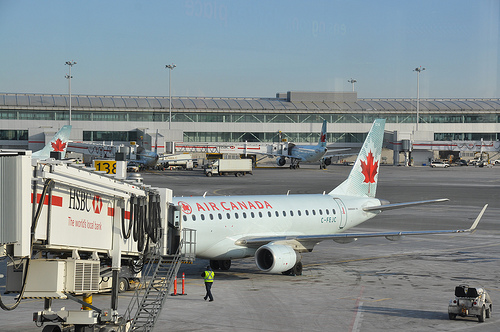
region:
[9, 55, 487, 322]
This is an airport scene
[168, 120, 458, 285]
This is an airliner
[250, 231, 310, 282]
This is one of the plane's engines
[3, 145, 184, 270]
This is a boarding tunnel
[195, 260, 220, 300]
This man is one of the ground crew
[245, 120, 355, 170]
Another plane is parked here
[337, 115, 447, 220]
This is the plane's tail section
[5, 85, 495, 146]
This is the terminal building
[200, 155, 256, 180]
A white truck is here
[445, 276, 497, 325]
A runway vehicle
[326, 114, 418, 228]
a red maple leaf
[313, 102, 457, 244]
the symbol of canada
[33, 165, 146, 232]
the hsbc logo on a runway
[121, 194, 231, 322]
this plane has a ladder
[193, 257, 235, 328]
a man in a safety jacket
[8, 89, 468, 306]
a plane at the terminal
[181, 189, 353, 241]
this is an air canada plane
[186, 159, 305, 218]
the font is red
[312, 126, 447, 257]
the logo on an airplane tail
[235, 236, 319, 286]
the engine of a jet plane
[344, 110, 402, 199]
Plane has red leaf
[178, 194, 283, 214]
Airplane says Air Canada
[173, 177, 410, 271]
Airplane is very white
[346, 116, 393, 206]
Tail fin has Canadian Red Maple leaf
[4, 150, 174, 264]
Plane loading chute is white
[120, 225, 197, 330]
Stairs to plane door are metal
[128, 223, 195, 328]
Stairs to plane door are gray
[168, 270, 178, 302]
Orange caution cone sitting on ground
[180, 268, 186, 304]
Orange caution cone sitting on ground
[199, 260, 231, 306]
Man wearing a bright green vest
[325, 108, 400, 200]
the tail of a plane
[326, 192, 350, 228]
the door of a plane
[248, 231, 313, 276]
the engine of a plane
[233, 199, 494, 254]
the wing of a plane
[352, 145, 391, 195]
a red maple leaf on the plane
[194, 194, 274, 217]
red writing on the plane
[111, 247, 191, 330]
a long gray staircase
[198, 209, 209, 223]
a window on the plane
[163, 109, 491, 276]
a large white plane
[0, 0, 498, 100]
a pale blue sky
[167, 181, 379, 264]
The plane is on the terminal runway.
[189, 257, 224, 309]
A man walking toward the plane.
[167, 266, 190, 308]
Two orange cones sitting on the concrete.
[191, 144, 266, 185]
A white truck driving on the runway.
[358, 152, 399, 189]
A red leaf on the tail of the airplane.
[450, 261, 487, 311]
A car sitting on the runway.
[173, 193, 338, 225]
Windows on the airplane.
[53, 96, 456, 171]
The building is part of the airport.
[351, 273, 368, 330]
A white line of the pavement.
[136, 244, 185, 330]
A staircase to the terminal walkway.